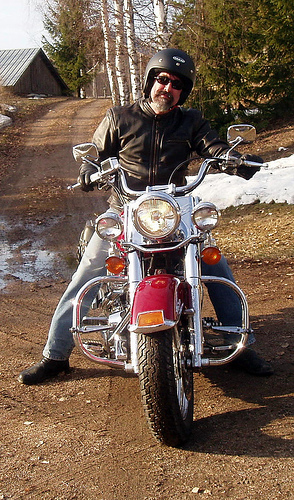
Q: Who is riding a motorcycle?
A: An older man.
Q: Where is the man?
A: On a dirt road.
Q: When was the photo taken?
A: On a cold day.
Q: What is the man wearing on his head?
A: Helmet.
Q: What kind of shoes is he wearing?
A: Black boots.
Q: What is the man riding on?
A: A red motorcycle.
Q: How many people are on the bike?
A: One.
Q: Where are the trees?
A: Beside the road, behind the man.